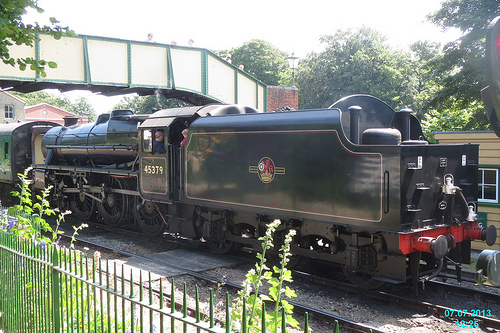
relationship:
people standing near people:
[142, 32, 158, 44] [169, 35, 179, 46]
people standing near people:
[169, 35, 179, 46] [184, 37, 196, 47]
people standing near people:
[184, 37, 196, 47] [220, 52, 233, 64]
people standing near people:
[220, 52, 233, 64] [236, 64, 246, 72]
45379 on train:
[144, 165, 164, 175] [32, 90, 494, 300]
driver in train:
[153, 131, 167, 154] [2, 81, 499, 286]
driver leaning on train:
[153, 131, 167, 154] [2, 81, 499, 286]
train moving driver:
[2, 81, 499, 286] [153, 131, 167, 154]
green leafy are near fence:
[10, 165, 54, 239] [6, 235, 137, 332]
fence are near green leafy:
[6, 235, 137, 332] [10, 165, 54, 239]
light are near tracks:
[482, 14, 498, 134] [85, 229, 492, 329]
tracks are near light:
[85, 229, 492, 329] [482, 14, 498, 134]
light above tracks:
[482, 14, 498, 134] [85, 229, 492, 329]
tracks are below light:
[85, 229, 492, 329] [482, 14, 498, 134]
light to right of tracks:
[482, 14, 498, 134] [85, 229, 492, 329]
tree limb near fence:
[4, 13, 79, 44] [2, 218, 340, 330]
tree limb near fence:
[0, 45, 57, 82] [2, 218, 340, 330]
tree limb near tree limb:
[411, 52, 468, 79] [458, 106, 490, 134]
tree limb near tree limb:
[458, 106, 490, 134] [422, 5, 487, 32]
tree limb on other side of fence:
[411, 52, 468, 79] [2, 218, 340, 330]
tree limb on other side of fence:
[458, 106, 490, 134] [2, 218, 340, 330]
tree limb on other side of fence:
[422, 5, 487, 32] [2, 218, 340, 330]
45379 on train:
[144, 165, 164, 175] [0, 93, 499, 291]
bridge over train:
[0, 21, 279, 120] [0, 93, 499, 291]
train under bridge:
[0, 93, 499, 291] [0, 21, 279, 120]